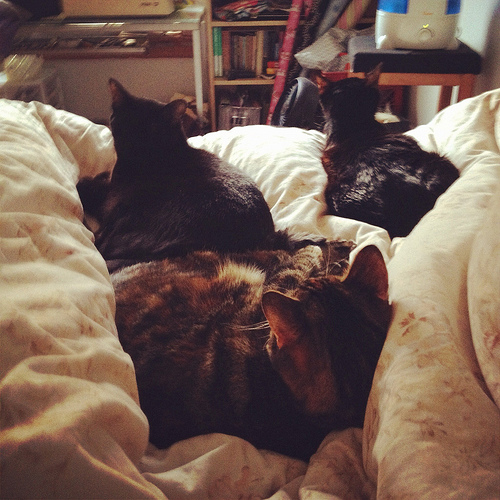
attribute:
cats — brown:
[75, 60, 463, 462]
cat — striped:
[106, 223, 406, 454]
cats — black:
[83, 58, 467, 271]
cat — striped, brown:
[113, 234, 390, 459]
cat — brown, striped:
[99, 228, 399, 470]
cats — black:
[79, 53, 464, 256]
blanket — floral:
[2, 90, 497, 494]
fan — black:
[272, 67, 319, 127]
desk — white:
[10, 1, 220, 131]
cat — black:
[313, 79, 458, 236]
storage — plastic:
[0, 50, 71, 104]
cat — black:
[74, 67, 291, 262]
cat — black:
[314, 70, 454, 223]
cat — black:
[79, 78, 299, 262]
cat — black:
[307, 62, 445, 233]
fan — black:
[274, 75, 318, 131]